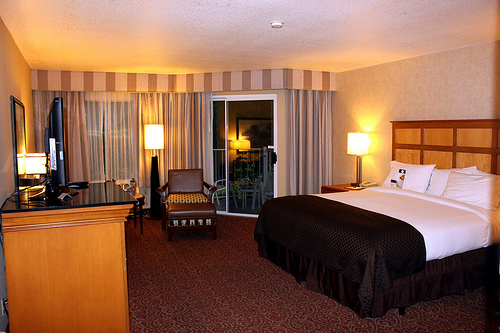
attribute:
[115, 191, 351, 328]
carpet — Brown 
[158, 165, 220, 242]
chair — red, white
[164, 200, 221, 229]
ottoman — leather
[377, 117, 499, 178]
headboard — brown, wood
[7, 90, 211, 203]
curtains — closed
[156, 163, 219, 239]
chair — brown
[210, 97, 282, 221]
glass door — sliding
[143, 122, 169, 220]
lamp — floor lamp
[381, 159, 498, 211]
pillowcases — white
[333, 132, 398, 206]
lamp — table lamp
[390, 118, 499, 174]
wood headboard — light, dark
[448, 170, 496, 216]
pillow — white, Bed pillow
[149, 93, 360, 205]
curtains — open 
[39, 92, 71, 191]
tv — black, flat screen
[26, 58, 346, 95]
striped valance — long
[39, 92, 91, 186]
drape — Brown 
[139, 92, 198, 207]
drape — Brown 